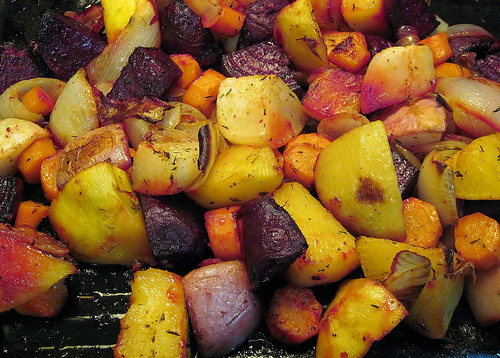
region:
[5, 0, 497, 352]
Multi-colored potatoes and vegetables roasting on a grill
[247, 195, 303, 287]
Purple potato on the grill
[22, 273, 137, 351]
Grates of the grill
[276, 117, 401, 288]
Yellow potatoes on the grill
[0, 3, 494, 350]
Food roasting on the grill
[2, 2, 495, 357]
A large pile of roasted fruit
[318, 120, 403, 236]
A slice of cooked lemon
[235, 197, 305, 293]
Purple chunk of fruit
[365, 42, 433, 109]
A piece of yellow fruit with a purple tip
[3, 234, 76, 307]
A piece of pink and yellow fruit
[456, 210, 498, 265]
Round piece of fruit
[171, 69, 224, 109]
An orange chunk of fruit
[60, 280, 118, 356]
Metal plate for a grill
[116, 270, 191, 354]
The food is yellow.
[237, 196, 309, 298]
The food is purple.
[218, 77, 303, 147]
The food is white.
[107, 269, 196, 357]
The food has spices.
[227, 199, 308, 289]
The food is diced.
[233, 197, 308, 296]
The food is in chunks.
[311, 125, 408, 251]
The food is cooked.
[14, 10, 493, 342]
The food is in a pile.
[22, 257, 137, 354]
The food is on a grill.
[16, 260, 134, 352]
The grill is black.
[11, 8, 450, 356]
Potatoes in the frying pan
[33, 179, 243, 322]
Potatoes in the frying pan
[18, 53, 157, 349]
Potatoes in the frying pan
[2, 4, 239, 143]
Potatoes in the frying pan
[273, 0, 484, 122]
Potatoes in the frying pan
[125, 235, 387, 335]
Potatoes in the frying pan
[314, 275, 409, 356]
orange piece of food on grill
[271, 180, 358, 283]
orange piece of food on grill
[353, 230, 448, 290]
orange piece of food on grill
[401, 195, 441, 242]
orange piece of food on grill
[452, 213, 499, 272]
orange piece of food on grill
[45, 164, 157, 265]
orange piece of food on grill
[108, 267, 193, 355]
orange piece of food on grill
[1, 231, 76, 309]
orange piece of food on grill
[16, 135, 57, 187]
orange piece of food on grill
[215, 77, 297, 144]
this is a potato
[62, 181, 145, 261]
this is a potatoe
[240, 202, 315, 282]
this is a arrow root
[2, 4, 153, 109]
Lightly grilled onions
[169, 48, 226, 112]
Two grilled orange carrots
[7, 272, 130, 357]
Metal grill rods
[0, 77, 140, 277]
Mixed grilled vegetables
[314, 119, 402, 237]
Grilled yellow lemon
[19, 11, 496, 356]
a pile of food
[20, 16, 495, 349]
the food has been sliced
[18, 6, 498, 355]
the food has been seasoned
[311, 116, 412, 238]
a wedge of food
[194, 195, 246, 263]
a slice of carrot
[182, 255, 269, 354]
a piece of onion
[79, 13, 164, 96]
the onion is white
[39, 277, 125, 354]
black surface under food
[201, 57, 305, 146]
a wedge of potato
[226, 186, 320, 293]
a purple wedge of food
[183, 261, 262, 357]
The largest pink piece of onion on the bottom.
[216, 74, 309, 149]
Middle most light yellow big chunk of potato.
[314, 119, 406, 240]
The largest chunk of yellow food.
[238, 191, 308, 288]
Burnt piece of food on top of a yellow wedge next to the largest onion.